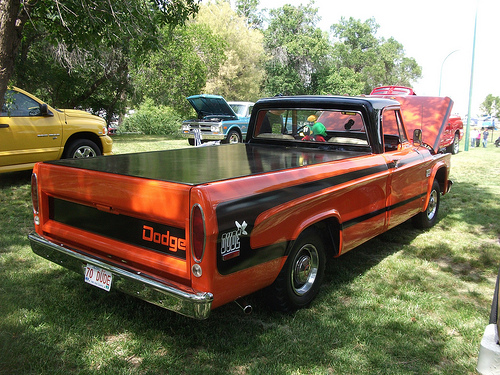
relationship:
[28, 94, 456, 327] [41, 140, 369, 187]
truck has black bed cover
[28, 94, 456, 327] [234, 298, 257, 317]
truck has a chrome exhaust pipe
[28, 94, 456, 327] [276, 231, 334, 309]
truck has a rear wheel and rear tire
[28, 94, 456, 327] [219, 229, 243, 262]
truck named dude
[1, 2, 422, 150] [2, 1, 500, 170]
large trees are in background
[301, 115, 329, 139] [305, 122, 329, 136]
man wearing a green shirt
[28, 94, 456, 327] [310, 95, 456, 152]
truck with an open hood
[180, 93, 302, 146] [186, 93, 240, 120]
truck with an open hood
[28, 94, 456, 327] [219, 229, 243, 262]
truck has writing with dude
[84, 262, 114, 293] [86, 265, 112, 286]
license plate has words 70 dude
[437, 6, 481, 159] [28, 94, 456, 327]
two light posts are in front of truck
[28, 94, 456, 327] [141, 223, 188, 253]
truck has word dodge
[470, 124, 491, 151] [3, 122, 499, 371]
people standing on grass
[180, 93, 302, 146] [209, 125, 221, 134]
truck has black headlights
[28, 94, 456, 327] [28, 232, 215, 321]
truck has chrome bumper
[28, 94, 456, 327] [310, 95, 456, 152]
truck has an open hood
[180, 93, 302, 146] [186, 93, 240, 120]
truck has an open hood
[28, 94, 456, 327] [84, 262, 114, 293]
truck has a license plate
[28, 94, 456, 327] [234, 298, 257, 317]
truck has chrome exhaust pipe